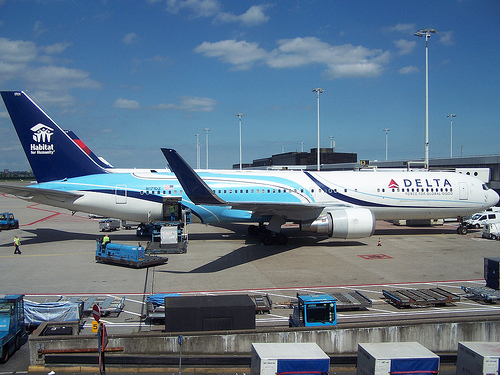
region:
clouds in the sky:
[269, 28, 371, 70]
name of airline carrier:
[395, 173, 457, 187]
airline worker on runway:
[5, 228, 53, 269]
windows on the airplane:
[237, 186, 279, 196]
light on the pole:
[308, 78, 328, 163]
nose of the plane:
[475, 177, 498, 216]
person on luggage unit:
[85, 232, 153, 276]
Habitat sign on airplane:
[21, 120, 58, 163]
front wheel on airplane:
[453, 220, 468, 245]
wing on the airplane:
[162, 157, 313, 221]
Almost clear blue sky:
[3, 5, 498, 140]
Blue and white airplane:
[3, 87, 498, 244]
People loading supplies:
[96, 182, 214, 279]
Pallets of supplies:
[241, 334, 498, 374]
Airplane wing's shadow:
[151, 233, 370, 281]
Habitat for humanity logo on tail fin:
[14, 115, 80, 177]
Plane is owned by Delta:
[371, 172, 471, 207]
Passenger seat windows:
[135, 183, 462, 200]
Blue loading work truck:
[277, 285, 348, 332]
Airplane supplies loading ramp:
[141, 182, 197, 269]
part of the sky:
[360, 23, 387, 39]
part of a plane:
[408, 186, 415, 188]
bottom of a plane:
[281, 230, 294, 245]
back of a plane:
[96, 198, 115, 221]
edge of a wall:
[208, 305, 220, 312]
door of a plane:
[463, 185, 466, 194]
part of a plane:
[418, 94, 458, 160]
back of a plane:
[32, 134, 49, 167]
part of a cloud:
[77, 65, 92, 82]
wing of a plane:
[343, 231, 362, 256]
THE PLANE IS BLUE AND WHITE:
[0, 90, 499, 253]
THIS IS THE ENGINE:
[300, 202, 380, 244]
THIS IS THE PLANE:
[1, 88, 499, 252]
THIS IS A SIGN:
[85, 300, 122, 373]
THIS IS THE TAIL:
[0, 84, 110, 186]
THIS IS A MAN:
[8, 231, 23, 258]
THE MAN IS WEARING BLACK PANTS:
[8, 232, 23, 257]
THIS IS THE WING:
[1, 83, 499, 250]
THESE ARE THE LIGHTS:
[191, 27, 461, 173]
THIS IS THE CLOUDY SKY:
[1, 0, 498, 187]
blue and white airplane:
[0, 88, 498, 242]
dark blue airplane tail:
[0, 89, 111, 184]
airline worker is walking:
[11, 234, 21, 252]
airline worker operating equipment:
[94, 231, 148, 267]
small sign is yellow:
[90, 320, 97, 331]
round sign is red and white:
[90, 303, 100, 321]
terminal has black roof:
[234, 147, 357, 167]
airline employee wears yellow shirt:
[12, 236, 22, 246]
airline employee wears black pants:
[13, 244, 20, 253]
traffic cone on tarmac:
[376, 236, 381, 245]